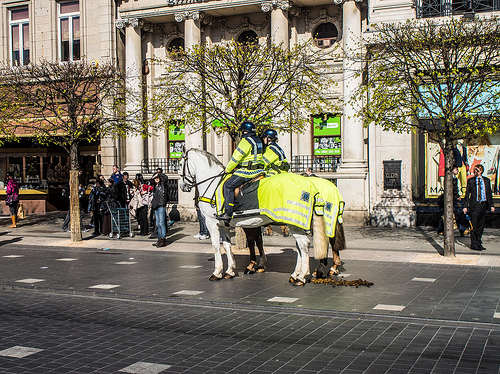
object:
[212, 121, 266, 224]
policeman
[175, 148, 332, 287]
horse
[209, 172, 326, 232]
blanket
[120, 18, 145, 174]
column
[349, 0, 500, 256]
tree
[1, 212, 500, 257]
sidewalk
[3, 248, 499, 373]
street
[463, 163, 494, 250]
man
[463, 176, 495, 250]
suit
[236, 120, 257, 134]
helmet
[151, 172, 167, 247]
person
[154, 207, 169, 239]
jeans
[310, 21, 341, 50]
window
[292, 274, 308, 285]
hooves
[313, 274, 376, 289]
horse droppings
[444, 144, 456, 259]
trunk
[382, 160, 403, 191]
plaque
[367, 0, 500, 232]
building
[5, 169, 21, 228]
woman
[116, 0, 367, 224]
building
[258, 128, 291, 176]
police officer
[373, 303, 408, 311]
tiles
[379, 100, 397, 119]
leaves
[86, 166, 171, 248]
people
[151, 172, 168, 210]
leather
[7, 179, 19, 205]
sweater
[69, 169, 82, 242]
base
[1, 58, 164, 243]
tree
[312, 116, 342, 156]
poster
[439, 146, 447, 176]
dress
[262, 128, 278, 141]
helmets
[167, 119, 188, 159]
poster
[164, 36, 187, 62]
window